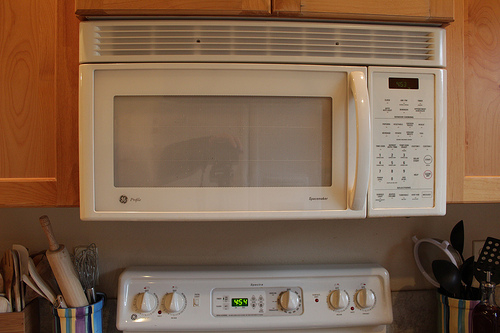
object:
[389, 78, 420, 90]
clock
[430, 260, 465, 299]
item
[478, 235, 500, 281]
item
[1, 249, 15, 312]
item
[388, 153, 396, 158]
controls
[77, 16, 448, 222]
microwave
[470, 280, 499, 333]
bottle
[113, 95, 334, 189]
screen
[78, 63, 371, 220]
door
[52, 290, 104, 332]
container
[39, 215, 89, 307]
kitchen utensils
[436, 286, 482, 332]
container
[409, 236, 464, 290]
kitchen utensils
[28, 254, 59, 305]
spatula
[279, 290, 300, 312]
knob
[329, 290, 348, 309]
knob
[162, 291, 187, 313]
knob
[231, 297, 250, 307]
clock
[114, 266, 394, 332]
oven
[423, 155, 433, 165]
botton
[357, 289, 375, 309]
knob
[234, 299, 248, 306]
4:54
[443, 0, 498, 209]
cabinets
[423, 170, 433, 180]
botton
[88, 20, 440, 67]
ventilation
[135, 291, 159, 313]
controls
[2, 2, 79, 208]
cabinet door